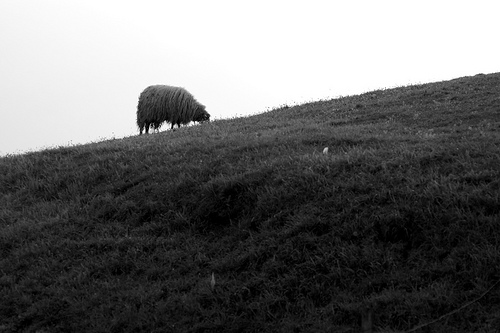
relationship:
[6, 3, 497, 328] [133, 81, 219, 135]
photo of sheep